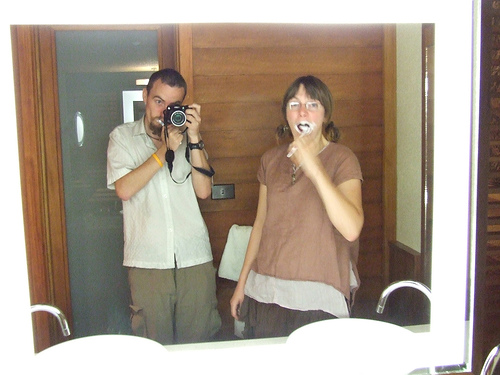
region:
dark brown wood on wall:
[225, 56, 256, 91]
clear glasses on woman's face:
[265, 88, 344, 116]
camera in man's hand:
[136, 90, 202, 155]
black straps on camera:
[154, 131, 230, 192]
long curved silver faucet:
[371, 273, 422, 318]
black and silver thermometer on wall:
[200, 181, 249, 197]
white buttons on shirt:
[156, 183, 179, 223]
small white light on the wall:
[68, 109, 89, 149]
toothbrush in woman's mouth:
[266, 105, 328, 152]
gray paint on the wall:
[68, 63, 116, 95]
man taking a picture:
[97, 65, 224, 240]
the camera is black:
[154, 99, 217, 186]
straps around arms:
[159, 126, 216, 186]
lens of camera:
[169, 105, 190, 127]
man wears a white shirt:
[96, 62, 228, 344]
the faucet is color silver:
[31, 297, 76, 345]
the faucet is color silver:
[373, 274, 431, 320]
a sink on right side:
[276, 275, 431, 374]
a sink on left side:
[30, 299, 171, 374]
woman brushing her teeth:
[240, 68, 378, 265]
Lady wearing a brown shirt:
[240, 81, 367, 340]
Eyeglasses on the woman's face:
[280, 91, 324, 118]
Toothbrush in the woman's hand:
[283, 123, 324, 164]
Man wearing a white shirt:
[94, 62, 236, 356]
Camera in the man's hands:
[149, 98, 217, 180]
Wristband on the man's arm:
[149, 147, 169, 172]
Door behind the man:
[11, 10, 210, 354]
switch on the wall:
[202, 176, 242, 208]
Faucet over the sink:
[369, 273, 436, 355]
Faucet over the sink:
[17, 301, 81, 372]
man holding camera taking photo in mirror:
[104, 68, 221, 338]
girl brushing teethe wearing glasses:
[232, 70, 373, 339]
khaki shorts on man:
[125, 253, 220, 340]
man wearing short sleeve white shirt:
[104, 118, 219, 275]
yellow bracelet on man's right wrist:
[151, 149, 172, 174]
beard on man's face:
[143, 99, 180, 138]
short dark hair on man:
[147, 69, 193, 102]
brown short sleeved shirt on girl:
[250, 132, 370, 288]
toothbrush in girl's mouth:
[285, 125, 321, 163]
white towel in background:
[218, 220, 265, 290]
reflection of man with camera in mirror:
[140, 69, 217, 169]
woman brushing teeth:
[273, 59, 356, 221]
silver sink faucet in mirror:
[370, 248, 430, 331]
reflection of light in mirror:
[71, 101, 119, 156]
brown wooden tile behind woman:
[213, 42, 248, 92]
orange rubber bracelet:
[147, 149, 170, 184]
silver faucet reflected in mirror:
[29, 270, 93, 345]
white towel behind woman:
[225, 207, 254, 271]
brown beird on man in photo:
[141, 118, 168, 140]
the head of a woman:
[264, 76, 338, 151]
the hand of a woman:
[278, 135, 330, 166]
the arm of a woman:
[297, 161, 391, 253]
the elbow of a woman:
[330, 219, 372, 254]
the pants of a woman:
[225, 282, 329, 340]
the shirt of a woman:
[244, 128, 372, 316]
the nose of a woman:
[295, 111, 316, 123]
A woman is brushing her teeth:
[246, 62, 366, 203]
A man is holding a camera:
[97, 51, 223, 207]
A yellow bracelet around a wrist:
[145, 145, 167, 180]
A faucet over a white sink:
[275, 270, 436, 370]